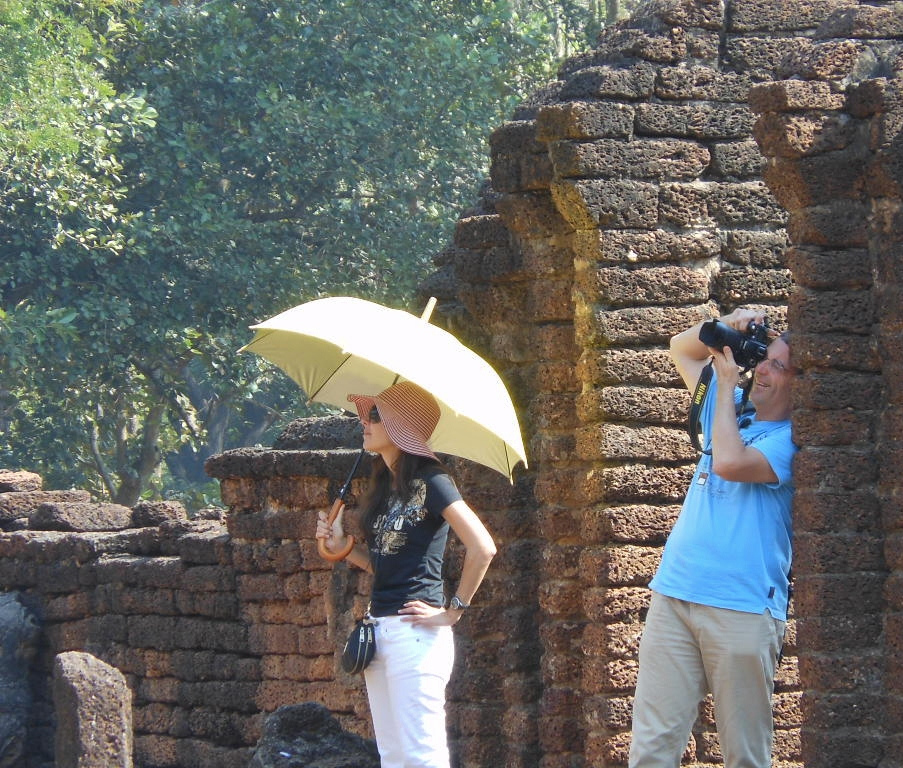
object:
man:
[629, 310, 797, 768]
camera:
[699, 318, 768, 376]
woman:
[315, 383, 500, 767]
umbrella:
[236, 297, 528, 488]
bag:
[342, 624, 377, 675]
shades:
[370, 404, 383, 423]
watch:
[449, 595, 470, 610]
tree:
[0, 0, 653, 521]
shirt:
[647, 367, 796, 619]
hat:
[347, 380, 443, 464]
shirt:
[363, 468, 466, 618]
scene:
[0, 0, 903, 768]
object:
[729, 643, 760, 660]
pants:
[629, 590, 787, 767]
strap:
[688, 354, 755, 454]